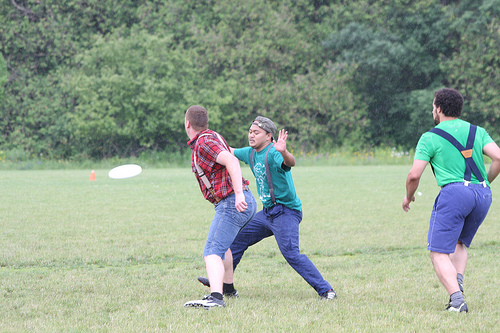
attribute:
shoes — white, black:
[174, 267, 264, 324]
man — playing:
[171, 111, 261, 232]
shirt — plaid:
[172, 126, 270, 183]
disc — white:
[99, 156, 149, 190]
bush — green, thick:
[0, 0, 500, 149]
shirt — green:
[265, 159, 319, 208]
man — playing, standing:
[182, 105, 257, 307]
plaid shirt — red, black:
[188, 128, 246, 201]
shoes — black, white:
[184, 293, 224, 308]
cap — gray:
[244, 111, 296, 138]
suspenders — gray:
[183, 140, 224, 220]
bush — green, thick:
[342, 32, 442, 123]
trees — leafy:
[36, 9, 436, 173]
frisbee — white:
[111, 157, 149, 187]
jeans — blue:
[225, 200, 332, 300]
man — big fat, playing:
[402, 89, 499, 321]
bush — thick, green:
[30, 28, 165, 133]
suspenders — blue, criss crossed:
[421, 117, 496, 187]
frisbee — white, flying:
[103, 157, 148, 181]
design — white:
[253, 164, 279, 216]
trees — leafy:
[0, 0, 498, 163]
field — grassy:
[1, 158, 497, 327]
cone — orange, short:
[83, 166, 100, 188]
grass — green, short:
[4, 157, 484, 318]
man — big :
[139, 85, 266, 287]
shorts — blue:
[424, 174, 495, 258]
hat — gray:
[250, 111, 281, 136]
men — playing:
[175, 83, 495, 309]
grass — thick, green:
[21, 202, 184, 293]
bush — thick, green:
[238, 20, 432, 157]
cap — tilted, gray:
[255, 109, 292, 163]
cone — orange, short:
[68, 157, 103, 194]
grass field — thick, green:
[302, 172, 389, 266]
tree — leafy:
[42, 15, 237, 163]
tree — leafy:
[218, 47, 383, 157]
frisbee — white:
[108, 165, 142, 180]